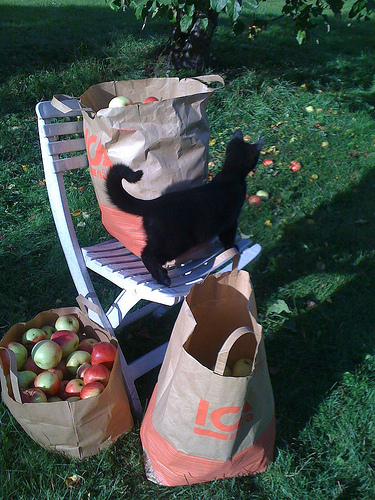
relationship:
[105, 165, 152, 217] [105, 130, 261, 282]
tail of cat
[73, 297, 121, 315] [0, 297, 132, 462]
handle of sack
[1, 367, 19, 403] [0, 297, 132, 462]
handle of sack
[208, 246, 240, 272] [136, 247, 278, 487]
handle of sack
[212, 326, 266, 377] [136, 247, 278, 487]
handle of sack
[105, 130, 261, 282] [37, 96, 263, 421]
cat on chair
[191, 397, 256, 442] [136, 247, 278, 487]
writing on sack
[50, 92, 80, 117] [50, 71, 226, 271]
handle of sack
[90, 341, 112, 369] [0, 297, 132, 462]
apple in sack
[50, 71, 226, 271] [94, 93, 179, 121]
sack of apples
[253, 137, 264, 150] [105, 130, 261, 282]
ear of cat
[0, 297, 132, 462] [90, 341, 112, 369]
sack of apple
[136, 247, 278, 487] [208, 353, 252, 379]
sack of apples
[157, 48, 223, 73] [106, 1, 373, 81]
trunk of tree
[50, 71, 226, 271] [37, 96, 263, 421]
sack on chair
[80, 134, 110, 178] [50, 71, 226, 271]
logo on sack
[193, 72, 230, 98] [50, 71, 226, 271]
handle on sack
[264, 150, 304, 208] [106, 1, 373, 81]
leaves from tree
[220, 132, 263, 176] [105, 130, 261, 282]
head of cat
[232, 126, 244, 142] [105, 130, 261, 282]
ear of cat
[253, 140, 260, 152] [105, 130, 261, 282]
ear of cat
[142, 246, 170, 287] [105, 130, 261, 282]
leg of cat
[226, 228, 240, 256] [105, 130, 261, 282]
leg of cat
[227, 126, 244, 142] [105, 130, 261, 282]
ear of cat